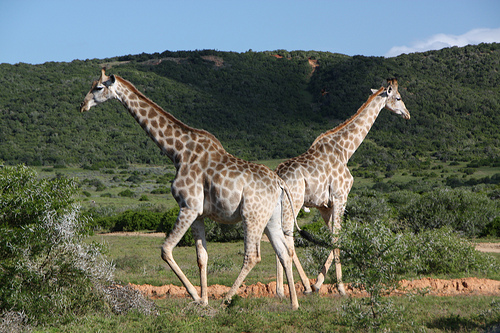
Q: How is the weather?
A: It is clear.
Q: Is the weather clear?
A: Yes, it is clear.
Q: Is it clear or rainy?
A: It is clear.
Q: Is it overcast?
A: No, it is clear.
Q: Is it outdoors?
A: Yes, it is outdoors.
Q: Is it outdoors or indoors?
A: It is outdoors.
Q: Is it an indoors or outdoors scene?
A: It is outdoors.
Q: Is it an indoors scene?
A: No, it is outdoors.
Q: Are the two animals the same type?
A: Yes, all the animals are giraffes.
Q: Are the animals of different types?
A: No, all the animals are giraffes.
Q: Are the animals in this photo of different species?
A: No, all the animals are giraffes.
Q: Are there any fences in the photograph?
A: No, there are no fences.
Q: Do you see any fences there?
A: No, there are no fences.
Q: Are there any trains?
A: No, there are no trains.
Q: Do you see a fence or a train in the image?
A: No, there are no trains or fences.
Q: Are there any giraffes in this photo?
A: Yes, there is a giraffe.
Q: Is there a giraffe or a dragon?
A: Yes, there is a giraffe.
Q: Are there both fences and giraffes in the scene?
A: No, there is a giraffe but no fences.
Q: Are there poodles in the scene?
A: No, there are no poodles.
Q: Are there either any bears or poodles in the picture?
A: No, there are no poodles or bears.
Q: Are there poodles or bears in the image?
A: No, there are no poodles or bears.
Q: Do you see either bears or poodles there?
A: No, there are no poodles or bears.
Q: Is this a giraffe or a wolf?
A: This is a giraffe.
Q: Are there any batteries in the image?
A: No, there are no batteries.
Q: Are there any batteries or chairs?
A: No, there are no batteries or chairs.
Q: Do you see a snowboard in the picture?
A: No, there are no snowboards.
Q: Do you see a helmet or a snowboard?
A: No, there are no snowboards or helmets.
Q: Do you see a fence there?
A: No, there are no fences.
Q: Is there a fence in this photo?
A: No, there are no fences.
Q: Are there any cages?
A: No, there are no cages.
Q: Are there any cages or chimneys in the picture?
A: No, there are no cages or chimneys.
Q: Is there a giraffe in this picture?
A: Yes, there is a giraffe.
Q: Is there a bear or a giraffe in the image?
A: Yes, there is a giraffe.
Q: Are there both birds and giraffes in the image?
A: No, there is a giraffe but no birds.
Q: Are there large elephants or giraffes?
A: Yes, there is a large giraffe.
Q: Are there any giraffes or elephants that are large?
A: Yes, the giraffe is large.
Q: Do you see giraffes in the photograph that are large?
A: Yes, there is a large giraffe.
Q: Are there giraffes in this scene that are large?
A: Yes, there is a giraffe that is large.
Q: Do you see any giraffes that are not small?
A: Yes, there is a large giraffe.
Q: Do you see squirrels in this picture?
A: No, there are no squirrels.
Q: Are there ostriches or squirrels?
A: No, there are no squirrels or ostriches.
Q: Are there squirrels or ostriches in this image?
A: No, there are no squirrels or ostriches.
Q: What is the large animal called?
A: The animal is a giraffe.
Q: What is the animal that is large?
A: The animal is a giraffe.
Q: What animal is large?
A: The animal is a giraffe.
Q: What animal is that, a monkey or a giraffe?
A: That is a giraffe.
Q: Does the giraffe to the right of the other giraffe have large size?
A: Yes, the giraffe is large.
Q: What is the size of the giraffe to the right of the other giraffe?
A: The giraffe is large.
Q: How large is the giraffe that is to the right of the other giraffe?
A: The giraffe is large.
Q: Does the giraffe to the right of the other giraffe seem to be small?
A: No, the giraffe is large.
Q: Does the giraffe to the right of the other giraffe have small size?
A: No, the giraffe is large.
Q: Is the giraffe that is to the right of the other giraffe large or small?
A: The giraffe is large.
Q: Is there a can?
A: No, there are no cans.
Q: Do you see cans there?
A: No, there are no cans.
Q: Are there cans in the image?
A: No, there are no cans.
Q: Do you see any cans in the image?
A: No, there are no cans.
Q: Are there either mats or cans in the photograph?
A: No, there are no cans or mats.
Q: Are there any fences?
A: No, there are no fences.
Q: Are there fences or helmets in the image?
A: No, there are no fences or helmets.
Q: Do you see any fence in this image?
A: No, there are no fences.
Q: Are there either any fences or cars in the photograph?
A: No, there are no fences or cars.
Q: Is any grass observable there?
A: Yes, there is grass.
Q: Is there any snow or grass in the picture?
A: Yes, there is grass.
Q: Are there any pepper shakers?
A: No, there are no pepper shakers.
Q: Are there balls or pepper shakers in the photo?
A: No, there are no pepper shakers or balls.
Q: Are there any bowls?
A: No, there are no bowls.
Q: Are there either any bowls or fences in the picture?
A: No, there are no bowls or fences.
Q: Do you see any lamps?
A: No, there are no lamps.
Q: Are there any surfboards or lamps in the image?
A: No, there are no lamps or surfboards.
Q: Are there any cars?
A: No, there are no cars.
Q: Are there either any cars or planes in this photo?
A: No, there are no cars or planes.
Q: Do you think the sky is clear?
A: Yes, the sky is clear.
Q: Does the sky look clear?
A: Yes, the sky is clear.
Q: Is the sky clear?
A: Yes, the sky is clear.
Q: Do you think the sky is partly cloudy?
A: No, the sky is clear.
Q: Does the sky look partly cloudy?
A: No, the sky is clear.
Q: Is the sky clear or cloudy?
A: The sky is clear.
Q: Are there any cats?
A: No, there are no cats.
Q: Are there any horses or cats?
A: No, there are no cats or horses.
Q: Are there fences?
A: No, there are no fences.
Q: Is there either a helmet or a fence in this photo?
A: No, there are no fences or helmets.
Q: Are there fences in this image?
A: No, there are no fences.